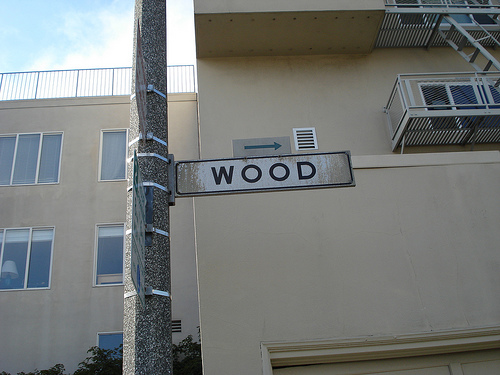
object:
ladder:
[436, 14, 500, 95]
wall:
[193, 150, 500, 375]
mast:
[120, 0, 173, 375]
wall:
[195, 46, 500, 160]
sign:
[168, 149, 358, 207]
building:
[192, 0, 499, 375]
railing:
[382, 70, 500, 140]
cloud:
[0, 0, 196, 100]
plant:
[73, 343, 120, 375]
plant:
[169, 333, 201, 373]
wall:
[0, 89, 201, 375]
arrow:
[244, 141, 282, 150]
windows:
[0, 129, 65, 189]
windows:
[416, 80, 499, 131]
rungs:
[121, 88, 172, 299]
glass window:
[0, 130, 64, 187]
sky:
[0, 0, 90, 66]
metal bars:
[0, 63, 196, 101]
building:
[0, 64, 202, 374]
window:
[97, 127, 128, 182]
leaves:
[86, 345, 102, 357]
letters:
[211, 161, 316, 185]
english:
[210, 161, 317, 187]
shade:
[1, 259, 18, 280]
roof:
[0, 91, 196, 103]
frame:
[255, 322, 500, 375]